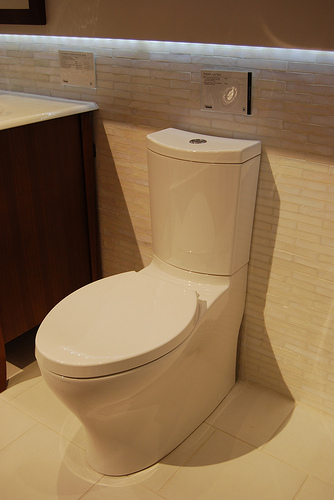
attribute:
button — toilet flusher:
[188, 137, 208, 145]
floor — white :
[2, 398, 333, 498]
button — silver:
[189, 135, 206, 145]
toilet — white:
[22, 123, 279, 477]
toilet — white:
[31, 124, 262, 474]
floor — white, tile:
[2, 374, 332, 498]